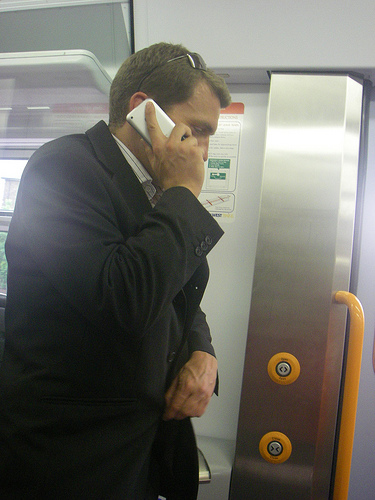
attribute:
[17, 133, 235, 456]
jacket — suit